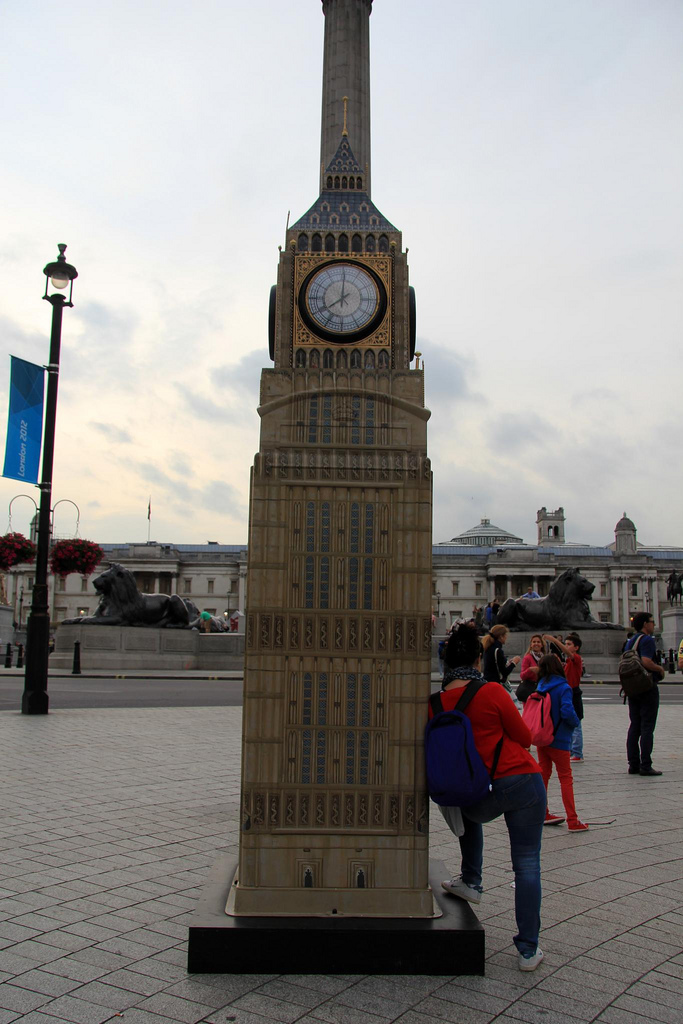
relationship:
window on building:
[294, 343, 311, 369] [201, 243, 433, 921]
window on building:
[158, 572, 186, 599] [70, 529, 223, 609]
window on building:
[204, 571, 223, 597] [148, 541, 246, 617]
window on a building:
[179, 578, 200, 595] [113, 524, 240, 618]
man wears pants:
[610, 601, 674, 782] [624, 686, 658, 762]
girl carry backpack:
[515, 641, 604, 839] [518, 681, 572, 753]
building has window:
[4, 529, 237, 633] [180, 571, 192, 593]